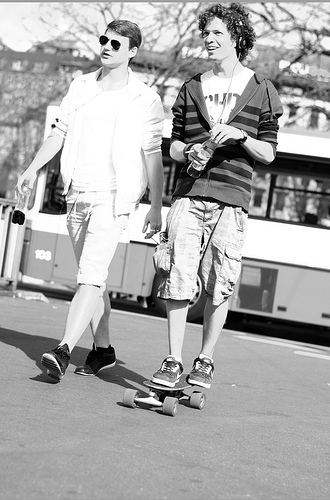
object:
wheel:
[189, 393, 207, 411]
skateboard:
[123, 371, 207, 417]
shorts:
[152, 194, 247, 305]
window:
[252, 189, 263, 209]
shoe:
[148, 355, 183, 388]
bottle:
[186, 137, 219, 180]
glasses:
[98, 33, 131, 52]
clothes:
[48, 66, 164, 214]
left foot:
[151, 355, 185, 388]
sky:
[0, 1, 330, 62]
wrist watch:
[236, 127, 247, 144]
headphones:
[238, 35, 248, 53]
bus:
[18, 102, 330, 330]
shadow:
[0, 326, 152, 408]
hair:
[198, 0, 256, 65]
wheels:
[161, 395, 179, 418]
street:
[0, 294, 330, 500]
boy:
[150, 0, 284, 391]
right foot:
[151, 355, 184, 390]